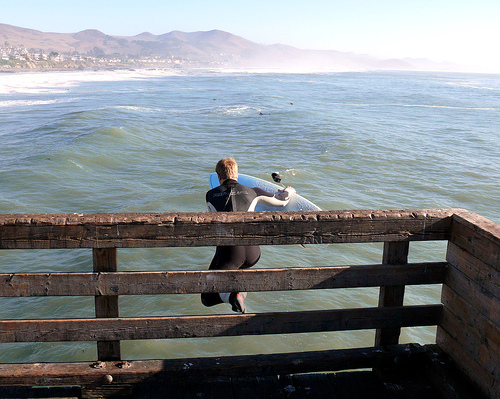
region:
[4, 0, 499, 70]
bright pale blue sky over mountains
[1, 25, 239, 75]
homes along lower half of mountain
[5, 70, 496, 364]
white surf at edge of greenish-gray ocean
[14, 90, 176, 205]
ocean forming mounds on water surface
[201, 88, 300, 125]
black birds encircling small round wave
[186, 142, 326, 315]
surfer holding blue board while jumping into water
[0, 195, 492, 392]
old brown wooden railing on elevated platform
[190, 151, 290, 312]
surfer wearing black wetsuit with white stripe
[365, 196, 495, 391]
railing connected to solid wood wall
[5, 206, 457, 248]
deep lines and cracks on top rail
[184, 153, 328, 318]
a person jumping off a pier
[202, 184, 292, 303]
a black and white wet suit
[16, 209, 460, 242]
a brown wooden beam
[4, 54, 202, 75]
houses in the distance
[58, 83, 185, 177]
ocean waves in the water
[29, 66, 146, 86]
a white sandy beach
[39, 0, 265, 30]
a clear blue sky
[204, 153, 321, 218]
a blue surf board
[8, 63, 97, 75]
a green and brown bank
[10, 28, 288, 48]
brown hills in the distance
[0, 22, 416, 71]
mountains in the background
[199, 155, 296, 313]
man jumping off dock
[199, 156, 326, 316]
man holding a surfboard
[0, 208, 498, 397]
dock above the ocean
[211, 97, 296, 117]
sharks swimming in the ocean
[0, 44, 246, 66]
beach town next to mountains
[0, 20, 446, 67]
rocky landscape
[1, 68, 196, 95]
waves crashing into the beach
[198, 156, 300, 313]
man wearing a black wetsuit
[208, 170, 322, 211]
blue surfboard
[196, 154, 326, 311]
surfer jumps into the water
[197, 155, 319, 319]
surfer jumps into the ocean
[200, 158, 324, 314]
surfer holds surfboard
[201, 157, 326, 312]
surfer wears wetsuit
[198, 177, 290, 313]
wetsuit is worn by human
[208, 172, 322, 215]
surfboard is held by human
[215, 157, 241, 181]
hair is cut short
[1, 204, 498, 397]
pier runs out across the ocean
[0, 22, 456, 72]
mountains are in the distance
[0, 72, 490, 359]
ocean is choppy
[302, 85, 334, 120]
a body of water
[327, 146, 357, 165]
a body of water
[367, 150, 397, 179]
a body of water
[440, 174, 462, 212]
a body of water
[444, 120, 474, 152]
a body of water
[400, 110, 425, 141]
a body of water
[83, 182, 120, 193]
a body of water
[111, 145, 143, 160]
a body of water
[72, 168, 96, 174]
a body of water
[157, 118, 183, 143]
a body of water